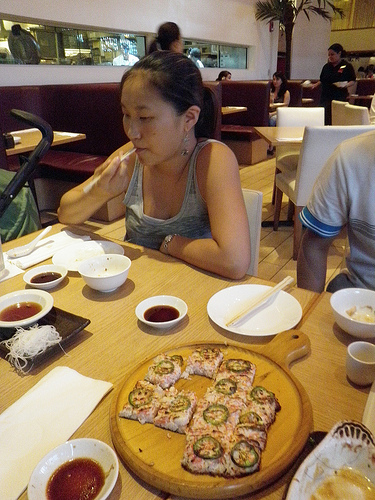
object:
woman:
[56, 50, 252, 280]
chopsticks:
[82, 148, 137, 194]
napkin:
[0, 365, 114, 500]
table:
[0, 220, 373, 500]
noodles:
[0, 322, 71, 376]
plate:
[0, 306, 90, 365]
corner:
[15, 337, 42, 371]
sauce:
[144, 305, 180, 323]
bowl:
[134, 295, 188, 330]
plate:
[206, 282, 304, 338]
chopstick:
[225, 275, 293, 327]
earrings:
[181, 130, 191, 156]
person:
[145, 21, 185, 55]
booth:
[203, 81, 271, 166]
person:
[310, 43, 357, 127]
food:
[299, 79, 316, 87]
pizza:
[118, 346, 282, 478]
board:
[109, 328, 314, 499]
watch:
[163, 232, 182, 255]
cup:
[346, 340, 374, 388]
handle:
[263, 328, 311, 364]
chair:
[273, 124, 375, 261]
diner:
[57, 50, 251, 281]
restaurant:
[1, 1, 373, 497]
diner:
[297, 129, 374, 292]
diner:
[267, 71, 290, 156]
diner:
[215, 70, 231, 82]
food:
[0, 264, 373, 500]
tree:
[254, 0, 346, 81]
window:
[0, 14, 146, 67]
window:
[181, 36, 248, 70]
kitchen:
[0, 12, 148, 67]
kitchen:
[182, 38, 248, 70]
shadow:
[233, 294, 279, 328]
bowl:
[77, 253, 132, 294]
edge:
[76, 253, 132, 279]